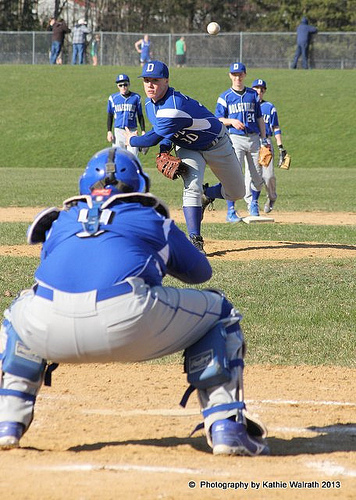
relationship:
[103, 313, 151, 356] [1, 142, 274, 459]
back pocket of catcher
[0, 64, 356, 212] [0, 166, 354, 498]
grass on baseball field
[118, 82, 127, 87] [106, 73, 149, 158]
sunglasses on player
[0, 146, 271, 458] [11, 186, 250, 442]
catcher wearing uniform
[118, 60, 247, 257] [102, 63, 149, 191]
person wearing uniform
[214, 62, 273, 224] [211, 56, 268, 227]
baseball player wearing uniform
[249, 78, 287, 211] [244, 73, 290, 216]
player wearing uniform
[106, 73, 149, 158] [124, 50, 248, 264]
player wearing uniform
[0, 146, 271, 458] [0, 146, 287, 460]
catcher wearing uniform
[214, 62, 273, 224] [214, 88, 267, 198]
baseball player wearing uniform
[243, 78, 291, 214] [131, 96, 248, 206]
player wearing uniform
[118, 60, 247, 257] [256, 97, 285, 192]
person wearing uniform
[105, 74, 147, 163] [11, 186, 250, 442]
player wearing uniform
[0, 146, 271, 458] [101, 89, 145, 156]
catcher wearing uniform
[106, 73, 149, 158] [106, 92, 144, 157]
player wearing uniform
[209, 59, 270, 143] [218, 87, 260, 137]
baseball player wearing uniform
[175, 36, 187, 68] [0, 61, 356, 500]
person standing on baseball field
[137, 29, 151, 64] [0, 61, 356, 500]
person standing on baseball field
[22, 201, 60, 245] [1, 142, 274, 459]
padding over catcher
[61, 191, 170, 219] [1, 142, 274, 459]
padding over catcher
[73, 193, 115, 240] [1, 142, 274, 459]
padding over catcher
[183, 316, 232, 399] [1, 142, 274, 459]
padding over catcher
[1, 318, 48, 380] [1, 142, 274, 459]
padding over catcher